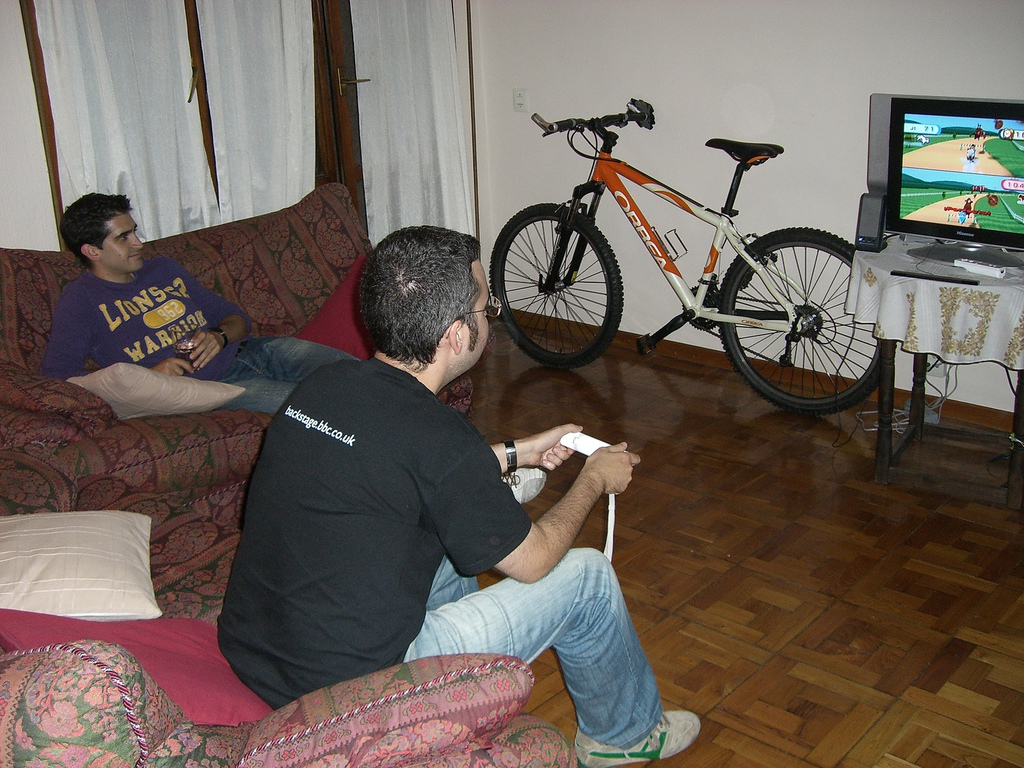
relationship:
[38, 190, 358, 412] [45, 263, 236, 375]
man wearing a blue shirt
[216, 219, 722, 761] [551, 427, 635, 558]
man holding controller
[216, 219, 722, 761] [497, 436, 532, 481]
man wearing a watch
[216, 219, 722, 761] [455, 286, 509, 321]
man wearing glasses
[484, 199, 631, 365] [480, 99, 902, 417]
tire of bike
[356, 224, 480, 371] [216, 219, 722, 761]
black hair of man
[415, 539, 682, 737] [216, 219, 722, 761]
blue pants on man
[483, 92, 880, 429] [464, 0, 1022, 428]
bike against wall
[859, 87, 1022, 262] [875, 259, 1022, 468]
tv sitting on a table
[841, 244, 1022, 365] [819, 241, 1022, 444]
table cloth on table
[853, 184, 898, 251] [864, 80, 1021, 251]
speaker sitting beside tv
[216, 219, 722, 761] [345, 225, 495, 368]
man wearing black hair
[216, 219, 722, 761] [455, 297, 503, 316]
man wearing glasses